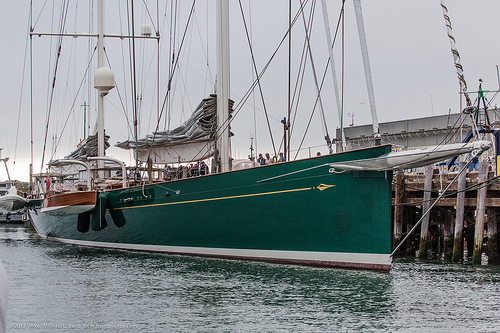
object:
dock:
[390, 162, 499, 263]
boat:
[26, 0, 494, 275]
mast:
[96, 0, 104, 178]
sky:
[0, 0, 495, 184]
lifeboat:
[39, 189, 97, 217]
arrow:
[105, 182, 337, 211]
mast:
[215, 1, 231, 172]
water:
[0, 214, 500, 333]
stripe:
[100, 180, 336, 213]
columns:
[390, 151, 484, 254]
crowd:
[187, 160, 208, 178]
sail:
[114, 94, 235, 165]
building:
[335, 109, 500, 176]